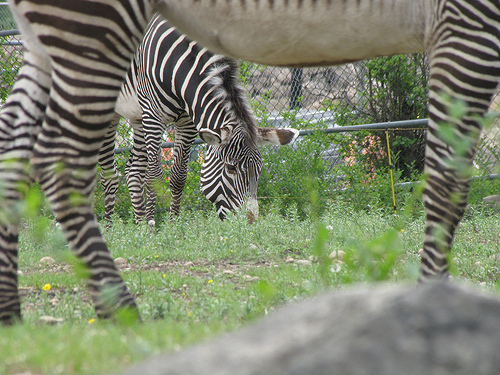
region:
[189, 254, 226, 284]
The grass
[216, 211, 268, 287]
The grass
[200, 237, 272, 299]
The grass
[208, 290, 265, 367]
The grass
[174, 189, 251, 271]
The grass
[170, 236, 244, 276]
The grass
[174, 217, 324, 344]
The grass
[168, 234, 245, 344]
The grass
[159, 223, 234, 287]
The grass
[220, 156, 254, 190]
A zebra's eye.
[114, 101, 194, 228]
A zebra's legs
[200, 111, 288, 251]
A zebra eating grass.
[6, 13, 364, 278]
Two zebra's in a field.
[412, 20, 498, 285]
Black and white zebra stripes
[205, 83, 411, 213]
A zebra in front of a fence.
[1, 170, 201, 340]
A zebra's hind feet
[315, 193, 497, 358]
A zebra standing behind a rock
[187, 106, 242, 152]
A zebra's ear.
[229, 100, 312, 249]
Green grass and a zebra.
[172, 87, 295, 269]
zebra grazing in a field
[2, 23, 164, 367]
hind legs of a zebra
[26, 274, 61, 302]
dandelion growing in the ground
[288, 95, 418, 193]
a chain link fence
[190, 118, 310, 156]
ears of a zebra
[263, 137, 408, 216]
tall weeds growing in the field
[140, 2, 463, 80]
the belly of a zebra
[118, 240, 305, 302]
rocks and dirt on the ground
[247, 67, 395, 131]
rocks on the other side of the fence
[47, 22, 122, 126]
black and white striped fur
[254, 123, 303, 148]
ear on a zebra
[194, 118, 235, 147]
ear on a zebra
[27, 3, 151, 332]
hind leg of a zebra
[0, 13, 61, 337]
hind leg on a zebra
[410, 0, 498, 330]
front leg on a zebra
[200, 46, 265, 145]
black and white zebra mane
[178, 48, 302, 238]
head of a zebra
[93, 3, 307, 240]
zebra eating some grass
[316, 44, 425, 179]
bush with green leaves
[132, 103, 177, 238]
front leg of a zebra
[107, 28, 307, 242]
a zebra grazing on weeds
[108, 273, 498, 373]
a large boulder in the foreground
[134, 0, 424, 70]
zebra's white under belly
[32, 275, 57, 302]
a flowering yellow dandelion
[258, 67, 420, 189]
a section of chain-link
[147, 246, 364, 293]
patch of soil and stone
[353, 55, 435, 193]
bush in the background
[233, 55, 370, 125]
a rocky wall beyond the fencing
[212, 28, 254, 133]
debra'a short bushy mane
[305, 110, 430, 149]
a steel railing along the display area